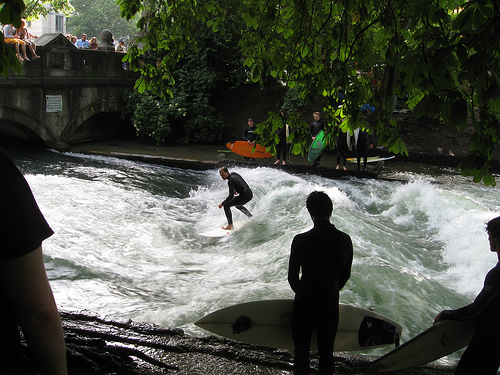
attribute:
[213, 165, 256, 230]
man — surfing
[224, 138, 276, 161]
surfboard — orange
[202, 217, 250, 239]
surfboard — white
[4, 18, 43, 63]
onlookers — sitting, watching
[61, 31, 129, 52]
onlookers — watching, standing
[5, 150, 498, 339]
stream — fast flowing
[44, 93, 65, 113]
sign — white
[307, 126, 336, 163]
surfboard — neon green, green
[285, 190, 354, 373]
man — standing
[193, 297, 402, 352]
surfboard — fiberglass, white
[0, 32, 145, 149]
bridge — stone, old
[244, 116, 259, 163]
man — waiting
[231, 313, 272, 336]
design — black